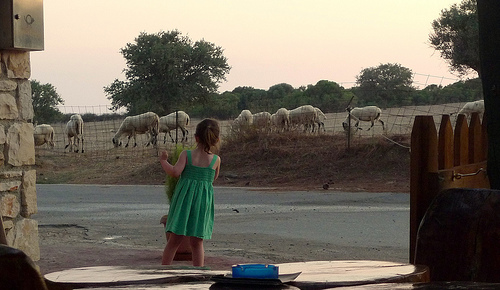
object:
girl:
[158, 117, 221, 267]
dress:
[165, 149, 218, 239]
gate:
[409, 112, 491, 264]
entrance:
[28, 0, 486, 282]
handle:
[452, 168, 487, 182]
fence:
[34, 73, 484, 162]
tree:
[31, 78, 65, 126]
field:
[35, 102, 482, 152]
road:
[29, 184, 410, 277]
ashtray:
[231, 263, 279, 279]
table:
[42, 259, 500, 289]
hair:
[194, 118, 220, 155]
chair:
[413, 187, 499, 282]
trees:
[102, 0, 500, 189]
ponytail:
[202, 126, 217, 155]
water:
[103, 235, 122, 239]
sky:
[28, 0, 480, 116]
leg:
[190, 236, 205, 267]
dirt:
[42, 224, 126, 243]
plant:
[165, 144, 199, 205]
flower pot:
[159, 215, 193, 254]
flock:
[33, 100, 484, 153]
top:
[410, 112, 490, 170]